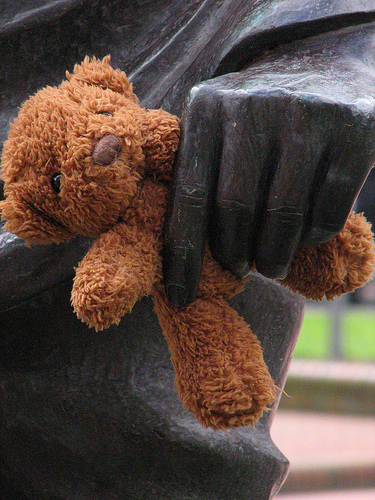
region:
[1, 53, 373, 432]
a brown teddy bear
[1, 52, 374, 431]
a teddy bear in the hand of a man statue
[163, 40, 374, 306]
the black hand of a statue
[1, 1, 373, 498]
the left side of a male statue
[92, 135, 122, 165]
a brown nose on the face of a teddy bear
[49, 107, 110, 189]
two black button eyes on the teddy bear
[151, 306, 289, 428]
the right leg on a brown teddy bear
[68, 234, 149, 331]
the right arm of the teddy bear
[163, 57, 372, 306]
the left hand on a black statue of a man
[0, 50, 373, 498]
a black statue of a man and a brown teddy bear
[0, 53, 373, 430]
the brown stuffed teddy bear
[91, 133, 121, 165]
the nose on the teddy bear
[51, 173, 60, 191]
the eye on the teddy bear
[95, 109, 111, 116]
the eye on the teddy bear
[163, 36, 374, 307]
the statue's hand holding the teddy bear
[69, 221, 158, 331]
the arm on the teddy bear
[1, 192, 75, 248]
the ear on the teddy bear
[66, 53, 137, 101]
the ear on the teddy bear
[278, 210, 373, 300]
the leg on the teddy bear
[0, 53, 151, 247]
the head on the teddy bear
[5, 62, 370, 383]
stuffed bear in statue hand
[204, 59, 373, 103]
light reflection on sculpture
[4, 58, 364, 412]
brown fur on stuffed toy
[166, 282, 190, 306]
nail of statue finger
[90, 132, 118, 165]
nose of bear face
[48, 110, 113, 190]
two black plastic eyes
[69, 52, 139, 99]
curved ear of bear head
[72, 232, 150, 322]
arm of stuffed bear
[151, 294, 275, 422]
leg of teddy bear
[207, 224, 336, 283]
curled fingers of statue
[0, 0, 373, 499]
Statue holding small teddy bear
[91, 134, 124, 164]
Brown nose on teddy bear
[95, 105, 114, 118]
Small black eye on teddy bear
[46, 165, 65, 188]
Small black eye on teddy bear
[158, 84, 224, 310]
Statue index finger touching teddy bear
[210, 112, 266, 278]
Statue middle finger touching teddy bear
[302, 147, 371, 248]
Statue pinky holding teddy bear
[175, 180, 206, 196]
Wrinkle on statue index finger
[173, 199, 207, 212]
Wrinkle on statue index finger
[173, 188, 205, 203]
Wrinkle on statue index finger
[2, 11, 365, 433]
teddy bear in the hand of a statue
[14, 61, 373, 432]
shaggy brown teddy bear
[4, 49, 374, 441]
bear with black eyes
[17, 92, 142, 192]
bear with marble eyes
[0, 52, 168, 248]
bear with dark brown nose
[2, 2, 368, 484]
black statue holding brown bear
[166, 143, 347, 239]
intricut detail of knuckles on hand of statue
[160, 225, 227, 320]
intricate detail of fingernail on statue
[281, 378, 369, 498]
step down in pavement behind statue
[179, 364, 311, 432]
string frayed on bear